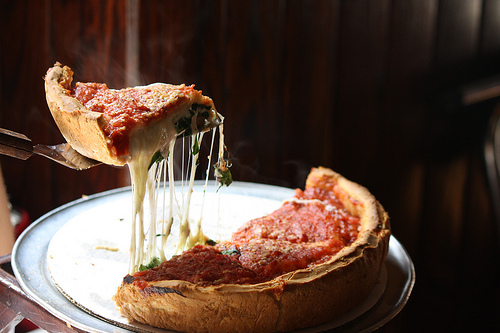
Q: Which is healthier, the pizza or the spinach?
A: The spinach is healthier than the pizza.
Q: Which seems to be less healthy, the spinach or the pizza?
A: The pizza is less healthy than the spinach.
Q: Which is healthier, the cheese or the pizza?
A: The cheese is healthier than the pizza.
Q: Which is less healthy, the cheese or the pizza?
A: The pizza is less healthy than the cheese.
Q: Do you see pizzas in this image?
A: Yes, there is a pizza.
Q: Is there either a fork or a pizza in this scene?
A: Yes, there is a pizza.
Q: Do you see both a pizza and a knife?
A: No, there is a pizza but no knives.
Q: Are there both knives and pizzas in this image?
A: No, there is a pizza but no knives.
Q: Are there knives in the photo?
A: No, there are no knives.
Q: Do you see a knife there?
A: No, there are no knives.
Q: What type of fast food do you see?
A: The fast food is a pizza.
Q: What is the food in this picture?
A: The food is a pizza.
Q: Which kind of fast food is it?
A: The food is a pizza.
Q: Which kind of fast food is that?
A: This is a pizza.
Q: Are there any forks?
A: No, there are no forks.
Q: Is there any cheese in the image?
A: Yes, there is cheese.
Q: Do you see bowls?
A: No, there are no bowls.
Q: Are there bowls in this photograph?
A: No, there are no bowls.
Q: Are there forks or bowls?
A: No, there are no bowls or forks.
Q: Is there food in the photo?
A: Yes, there is food.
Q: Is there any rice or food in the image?
A: Yes, there is food.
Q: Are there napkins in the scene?
A: No, there are no napkins.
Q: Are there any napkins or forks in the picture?
A: No, there are no napkins or forks.